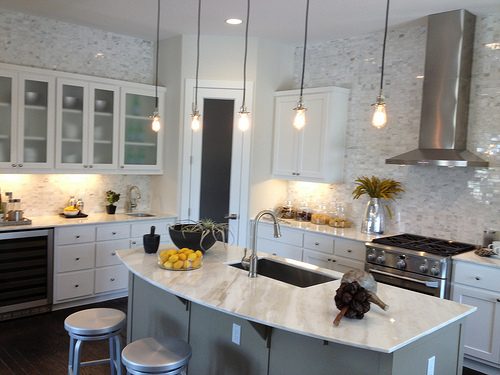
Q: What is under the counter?
A: Two Stools.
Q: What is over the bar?
A: Lights.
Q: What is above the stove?
A: Silver exhaust fan.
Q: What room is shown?
A: Kitchen.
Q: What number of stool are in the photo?
A: 2.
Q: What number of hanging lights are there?
A: 5.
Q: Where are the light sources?
A: Ceiling and under cabinets.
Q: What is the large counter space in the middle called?
A: Island.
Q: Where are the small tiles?
A: On the walls.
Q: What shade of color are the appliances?
A: Silver.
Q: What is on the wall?
A: Cabinets.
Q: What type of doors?
A: Glass doors.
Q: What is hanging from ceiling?
A: Light fixture.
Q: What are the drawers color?
A: White.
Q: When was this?
A: Daytime.